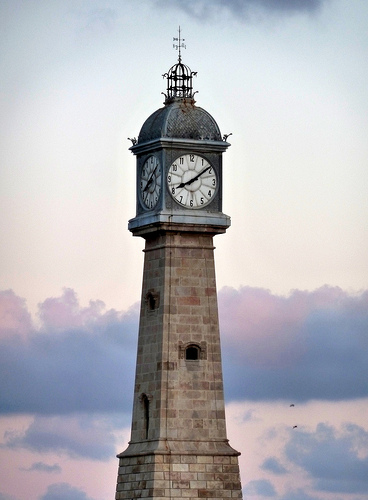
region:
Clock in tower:
[160, 149, 220, 211]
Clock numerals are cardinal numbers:
[164, 150, 224, 213]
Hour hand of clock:
[174, 173, 198, 191]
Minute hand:
[185, 162, 214, 185]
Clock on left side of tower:
[129, 150, 164, 214]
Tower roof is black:
[134, 97, 228, 144]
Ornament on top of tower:
[159, 16, 201, 106]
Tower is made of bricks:
[110, 230, 249, 499]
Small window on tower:
[130, 385, 160, 445]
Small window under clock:
[177, 337, 209, 383]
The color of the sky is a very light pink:
[264, 164, 307, 256]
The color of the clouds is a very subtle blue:
[84, 338, 119, 405]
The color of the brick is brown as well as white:
[154, 310, 220, 425]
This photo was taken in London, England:
[88, 23, 277, 484]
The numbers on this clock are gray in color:
[163, 136, 232, 259]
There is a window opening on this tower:
[183, 323, 217, 369]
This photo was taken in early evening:
[133, 58, 279, 462]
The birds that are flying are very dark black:
[289, 394, 314, 436]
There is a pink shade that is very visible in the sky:
[17, 474, 24, 489]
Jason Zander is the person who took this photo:
[69, 158, 308, 480]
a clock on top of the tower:
[166, 152, 218, 209]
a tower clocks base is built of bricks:
[115, 23, 240, 496]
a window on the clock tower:
[181, 342, 205, 361]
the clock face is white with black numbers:
[165, 153, 217, 210]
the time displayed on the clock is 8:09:
[167, 154, 219, 209]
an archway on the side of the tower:
[138, 392, 153, 441]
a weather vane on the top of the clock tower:
[172, 23, 187, 61]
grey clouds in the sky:
[217, 283, 367, 401]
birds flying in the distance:
[288, 401, 294, 407]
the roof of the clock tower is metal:
[129, 102, 229, 146]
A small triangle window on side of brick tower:
[175, 334, 246, 372]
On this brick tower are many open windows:
[129, 280, 244, 448]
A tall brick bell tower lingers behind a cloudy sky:
[108, 19, 267, 496]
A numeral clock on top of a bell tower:
[114, 142, 284, 219]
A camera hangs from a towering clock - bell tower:
[221, 126, 237, 148]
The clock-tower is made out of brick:
[117, 17, 285, 494]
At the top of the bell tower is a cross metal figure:
[145, 21, 219, 104]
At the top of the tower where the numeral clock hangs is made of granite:
[124, 50, 268, 231]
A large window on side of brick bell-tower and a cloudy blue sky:
[103, 361, 271, 495]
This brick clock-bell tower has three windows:
[109, 22, 250, 496]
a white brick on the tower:
[171, 462, 189, 472]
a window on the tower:
[173, 337, 208, 365]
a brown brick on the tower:
[156, 360, 177, 372]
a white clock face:
[164, 152, 218, 210]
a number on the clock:
[187, 152, 197, 165]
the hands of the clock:
[174, 165, 211, 193]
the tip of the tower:
[168, 21, 190, 63]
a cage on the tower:
[162, 60, 195, 102]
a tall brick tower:
[107, 227, 245, 498]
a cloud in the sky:
[0, 279, 366, 413]